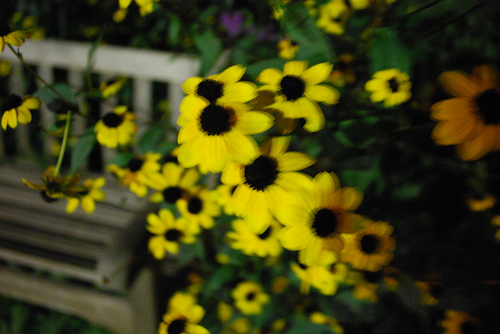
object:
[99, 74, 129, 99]
flower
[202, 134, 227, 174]
petal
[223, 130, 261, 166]
petal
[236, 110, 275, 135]
petal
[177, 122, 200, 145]
petal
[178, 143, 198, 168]
petal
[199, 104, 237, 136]
center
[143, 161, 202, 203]
flower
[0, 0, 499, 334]
plant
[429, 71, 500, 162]
flower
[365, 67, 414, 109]
flower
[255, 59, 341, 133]
flower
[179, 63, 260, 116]
flower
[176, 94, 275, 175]
flower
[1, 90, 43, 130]
flower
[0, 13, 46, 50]
flower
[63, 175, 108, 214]
flower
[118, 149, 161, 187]
flower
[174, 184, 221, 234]
flower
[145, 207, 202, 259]
flower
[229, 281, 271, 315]
flower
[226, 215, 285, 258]
flower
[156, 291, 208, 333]
flower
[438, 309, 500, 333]
flower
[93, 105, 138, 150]
flower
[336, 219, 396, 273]
flower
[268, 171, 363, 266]
flower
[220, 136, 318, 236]
flowers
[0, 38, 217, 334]
seating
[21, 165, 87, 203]
flower